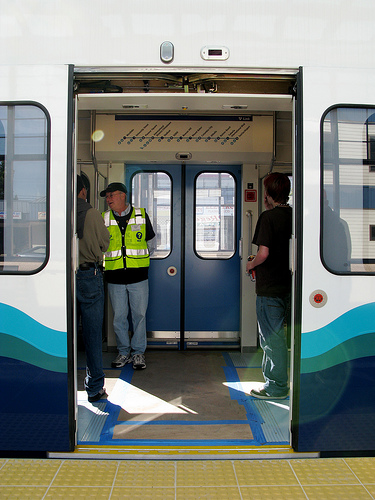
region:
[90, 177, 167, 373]
man in yellow vest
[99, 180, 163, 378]
man in reflective safety vest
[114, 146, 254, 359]
closed train doors with wiindows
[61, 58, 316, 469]
open train doorway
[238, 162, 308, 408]
man in black shirt and blue jeans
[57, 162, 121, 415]
person wearing grey shirt and blue jeans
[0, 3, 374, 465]
train car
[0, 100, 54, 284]
window to the left of train door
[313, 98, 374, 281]
window to the right of train door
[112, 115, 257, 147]
guide for stops this train makes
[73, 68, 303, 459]
the open door of a subway train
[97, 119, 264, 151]
the route of a subway line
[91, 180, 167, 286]
a man wearing a yellow vest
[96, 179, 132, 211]
a man wearing a baseball cap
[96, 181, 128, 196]
a black baseball cap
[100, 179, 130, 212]
a man wearing glasses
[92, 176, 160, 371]
a wearing blue jeans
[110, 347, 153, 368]
white and black tennis shoes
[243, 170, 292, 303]
a man wearing a black t-shirt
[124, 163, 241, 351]
the doors on a subway train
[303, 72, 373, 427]
Door on a train with a window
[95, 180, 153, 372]
Man wearing reflective vest and hat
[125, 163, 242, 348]
Closed doors on a train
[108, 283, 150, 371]
Blue jeans and white shoes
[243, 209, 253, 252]
Bar on train to hold on to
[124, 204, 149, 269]
Green reflective vest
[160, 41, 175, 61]
Small grey and white light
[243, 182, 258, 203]
Red fire alarm for emergencies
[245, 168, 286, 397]
Standing man holding a drink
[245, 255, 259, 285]
A canned drink being held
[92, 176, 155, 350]
a man standing on a train in a reflective vest.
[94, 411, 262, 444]
blue line painted on a train floor.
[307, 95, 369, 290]
a window on the side of a train.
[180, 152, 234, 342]
a door on the side of a train.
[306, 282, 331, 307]
A handle on a vehicle door.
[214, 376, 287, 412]
light shining on a train floor.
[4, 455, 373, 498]
a loading platform for a train.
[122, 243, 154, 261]
a white reflective line on a jacket.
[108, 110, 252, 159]
a line above a train entrance.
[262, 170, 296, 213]
a man with dark hair.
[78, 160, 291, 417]
three man inside a train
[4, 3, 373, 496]
a passenger train in a subway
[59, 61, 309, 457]
door of train is open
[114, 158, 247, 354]
blue door on back of train is close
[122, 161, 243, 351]
blue door of train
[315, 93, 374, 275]
window of train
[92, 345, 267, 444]
blue lines on floor of train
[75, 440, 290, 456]
a yellow line on doorstep of train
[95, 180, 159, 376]
man wears a green vest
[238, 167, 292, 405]
man wears a black tee shirt